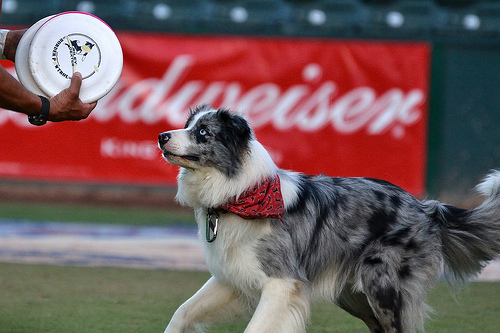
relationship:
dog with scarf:
[154, 103, 496, 327] [210, 175, 297, 222]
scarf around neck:
[210, 175, 297, 222] [180, 154, 304, 224]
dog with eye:
[154, 103, 496, 327] [197, 127, 208, 135]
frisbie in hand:
[13, 12, 124, 101] [44, 82, 102, 124]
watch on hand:
[30, 91, 51, 126] [44, 82, 102, 124]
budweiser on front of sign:
[10, 73, 416, 139] [5, 31, 426, 187]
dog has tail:
[154, 103, 496, 327] [426, 167, 499, 276]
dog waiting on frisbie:
[154, 103, 496, 327] [13, 12, 124, 101]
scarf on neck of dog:
[210, 175, 297, 222] [154, 103, 496, 327]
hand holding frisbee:
[44, 82, 102, 124] [30, 18, 123, 98]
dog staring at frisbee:
[154, 103, 496, 327] [30, 18, 123, 98]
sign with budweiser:
[5, 31, 426, 187] [10, 73, 416, 139]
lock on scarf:
[201, 208, 220, 242] [210, 175, 297, 222]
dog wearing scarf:
[154, 103, 496, 327] [210, 175, 297, 222]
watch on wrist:
[30, 91, 51, 126] [23, 85, 59, 132]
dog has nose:
[154, 103, 496, 327] [155, 131, 174, 144]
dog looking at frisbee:
[154, 103, 496, 327] [30, 18, 123, 98]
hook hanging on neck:
[201, 208, 220, 242] [180, 154, 304, 224]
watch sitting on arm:
[30, 91, 51, 126] [2, 62, 51, 124]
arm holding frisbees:
[2, 62, 51, 124] [13, 12, 124, 101]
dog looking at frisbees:
[154, 103, 496, 327] [13, 12, 124, 101]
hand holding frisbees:
[44, 82, 102, 124] [13, 12, 124, 101]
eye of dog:
[197, 127, 208, 135] [154, 103, 496, 327]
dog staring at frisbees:
[154, 103, 496, 327] [13, 12, 124, 101]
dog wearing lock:
[154, 103, 496, 327] [201, 208, 220, 242]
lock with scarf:
[201, 208, 220, 242] [210, 175, 297, 222]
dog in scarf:
[154, 103, 496, 327] [210, 175, 297, 222]